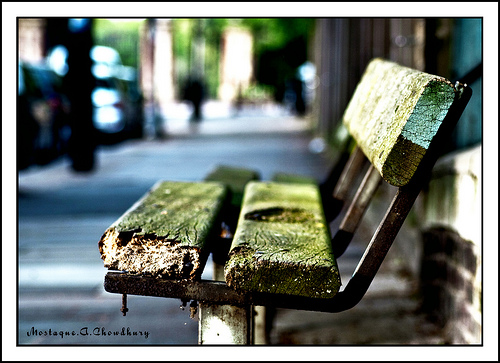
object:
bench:
[96, 55, 473, 344]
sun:
[101, 20, 317, 133]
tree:
[93, 18, 315, 98]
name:
[27, 326, 150, 339]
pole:
[42, 17, 97, 172]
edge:
[97, 227, 201, 277]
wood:
[223, 180, 342, 300]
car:
[18, 46, 148, 168]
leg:
[198, 301, 250, 344]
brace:
[104, 80, 473, 312]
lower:
[18, 238, 199, 345]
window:
[450, 18, 482, 148]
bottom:
[34, 301, 141, 345]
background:
[82, 29, 291, 160]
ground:
[18, 115, 454, 345]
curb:
[16, 113, 235, 179]